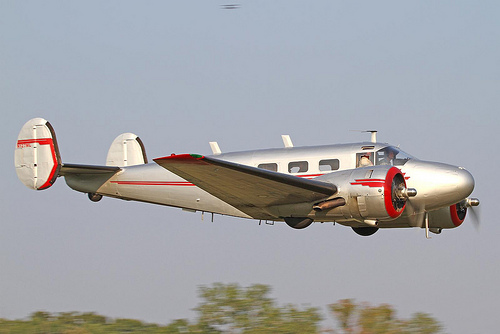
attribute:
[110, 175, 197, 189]
stripe — red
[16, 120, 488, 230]
airplaine — is silver, is red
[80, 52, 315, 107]
sky — blue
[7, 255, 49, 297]
cloud — white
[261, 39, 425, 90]
sky — blue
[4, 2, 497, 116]
sky — blue, white,  blue,  clear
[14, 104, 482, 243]
jet — silver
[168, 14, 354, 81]
clouds — white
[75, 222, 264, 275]
sky — blue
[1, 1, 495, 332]
sky — clear, blue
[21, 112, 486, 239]
jet — is red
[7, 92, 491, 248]
plane — is silver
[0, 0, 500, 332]
blue skies — is blue, is clear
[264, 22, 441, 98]
clouds sky — white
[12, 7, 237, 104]
clouds sky — white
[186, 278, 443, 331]
trees — old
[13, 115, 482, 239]
plane — flying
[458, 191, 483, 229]
propellor — spinning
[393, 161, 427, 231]
propellor — spinning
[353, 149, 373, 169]
window — is small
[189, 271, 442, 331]
trees — green